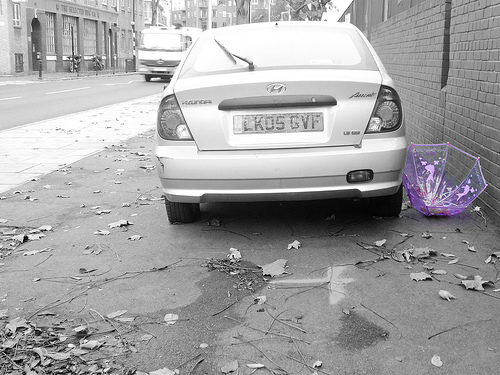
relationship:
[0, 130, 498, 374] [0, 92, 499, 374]
leaves over ground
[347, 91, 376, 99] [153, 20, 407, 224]
sign behind car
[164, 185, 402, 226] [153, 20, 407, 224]
tires connected to car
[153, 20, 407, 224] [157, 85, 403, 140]
car has tail lights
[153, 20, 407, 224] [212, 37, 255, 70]
car has wiper blade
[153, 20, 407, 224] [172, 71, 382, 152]
car has trunk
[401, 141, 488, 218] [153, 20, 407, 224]
umbrella next to car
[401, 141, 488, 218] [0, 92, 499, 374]
umbrella on top of ground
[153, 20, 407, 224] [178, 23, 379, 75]
car has back window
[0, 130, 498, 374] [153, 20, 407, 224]
leaves around car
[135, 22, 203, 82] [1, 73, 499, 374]
bus driving through street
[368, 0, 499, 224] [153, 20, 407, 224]
wall next to car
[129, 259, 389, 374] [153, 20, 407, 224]
oil spots behind car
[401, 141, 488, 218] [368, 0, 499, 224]
umbrella next to wall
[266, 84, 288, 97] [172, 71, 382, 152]
logo on trunk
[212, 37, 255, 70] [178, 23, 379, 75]
wiper blade on back window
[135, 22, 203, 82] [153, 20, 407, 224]
bus in front of car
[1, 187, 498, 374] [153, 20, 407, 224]
twigs around car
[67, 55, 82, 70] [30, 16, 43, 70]
bike near archway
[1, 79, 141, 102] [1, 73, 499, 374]
stripe in middle of street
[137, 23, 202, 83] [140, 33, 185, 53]
bus has windshield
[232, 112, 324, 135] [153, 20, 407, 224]
license plate behind car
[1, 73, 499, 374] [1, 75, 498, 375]
street made of concrete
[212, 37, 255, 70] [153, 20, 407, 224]
wiper blade behind car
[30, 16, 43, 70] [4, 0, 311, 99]
archway in building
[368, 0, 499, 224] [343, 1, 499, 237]
wall of building